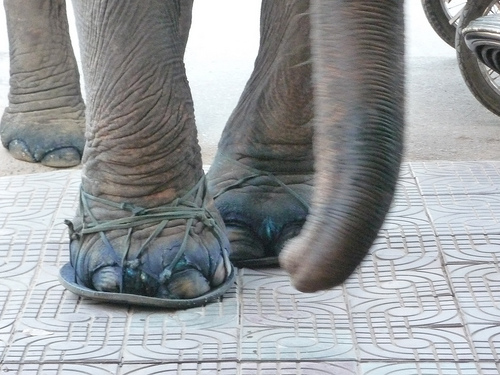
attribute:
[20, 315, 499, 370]
ground designs — gray, silver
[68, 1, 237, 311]
leg — Rear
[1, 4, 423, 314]
elephant — brownish, grayish, big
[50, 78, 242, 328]
foot —  right, Rear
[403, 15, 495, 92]
wheels — black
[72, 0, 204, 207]
gray skin — wrinkled